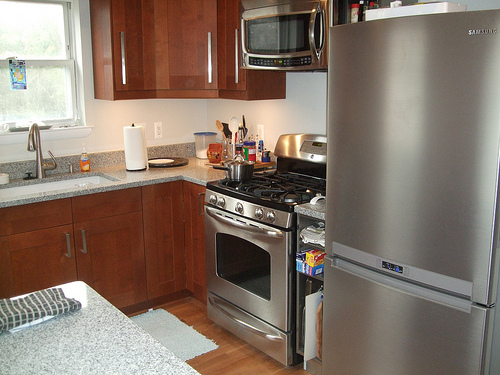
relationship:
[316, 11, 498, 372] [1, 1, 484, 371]
refrigerator in kitchen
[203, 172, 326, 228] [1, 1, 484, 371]
burner in kitchen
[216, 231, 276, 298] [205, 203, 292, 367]
window in oven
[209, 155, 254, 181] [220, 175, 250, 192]
pot sitting on burner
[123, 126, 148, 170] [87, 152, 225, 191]
paper towel on counter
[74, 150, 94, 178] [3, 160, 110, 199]
bottle on sink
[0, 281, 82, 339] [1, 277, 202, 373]
towel on counter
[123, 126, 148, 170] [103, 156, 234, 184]
paper towel on counter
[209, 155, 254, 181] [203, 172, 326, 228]
pot on burner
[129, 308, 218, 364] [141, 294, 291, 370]
rug on floor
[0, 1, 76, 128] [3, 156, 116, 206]
kitchen window over sink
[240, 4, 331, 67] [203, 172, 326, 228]
microwave over burner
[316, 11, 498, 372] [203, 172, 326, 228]
refrigerator to right of burner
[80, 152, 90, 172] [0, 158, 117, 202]
bottle by sink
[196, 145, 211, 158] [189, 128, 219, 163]
substance in container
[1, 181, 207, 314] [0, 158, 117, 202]
cabinet under sink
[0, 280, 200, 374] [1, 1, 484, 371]
counter mounted into kitchen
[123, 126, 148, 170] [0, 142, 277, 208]
paper towel sitting on top of counter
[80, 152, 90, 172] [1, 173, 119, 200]
bottle sitting next to sink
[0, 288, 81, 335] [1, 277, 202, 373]
towel lying on top of counter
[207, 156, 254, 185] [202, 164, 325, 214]
pot sitting on top of stove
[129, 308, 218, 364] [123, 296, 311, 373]
rug lying on top of floor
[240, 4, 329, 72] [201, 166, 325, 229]
microwave hanging above stove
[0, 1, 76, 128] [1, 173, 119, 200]
kitchen window mounted above sink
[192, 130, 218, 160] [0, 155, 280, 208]
canister sitting on top of counter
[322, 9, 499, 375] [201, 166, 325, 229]
refrigerator standing next to stove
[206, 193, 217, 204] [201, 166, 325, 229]
knob controlling stove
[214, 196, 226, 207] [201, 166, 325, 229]
knob controlling stove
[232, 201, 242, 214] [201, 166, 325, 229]
knob controlling stove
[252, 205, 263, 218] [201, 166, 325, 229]
knob controlling stove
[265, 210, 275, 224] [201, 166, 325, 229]
knob controlling stove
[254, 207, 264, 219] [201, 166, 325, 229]
knob controlling stove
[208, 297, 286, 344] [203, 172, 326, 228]
handle mounted on burner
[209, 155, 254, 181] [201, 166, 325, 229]
pot sitting on top of stove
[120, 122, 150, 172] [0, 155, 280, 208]
paper towel sitting on top of counter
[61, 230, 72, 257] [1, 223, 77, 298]
handle mounted on cabinet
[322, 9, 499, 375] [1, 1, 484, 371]
refrigerator standing inside kitchen